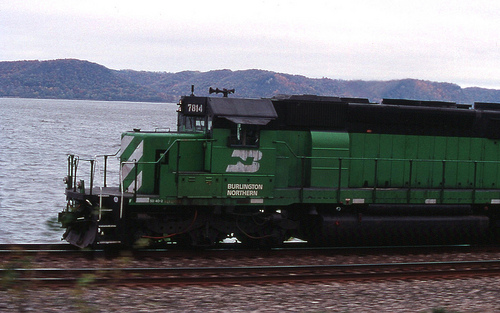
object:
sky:
[0, 0, 500, 91]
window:
[192, 119, 203, 130]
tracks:
[0, 259, 497, 280]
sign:
[225, 149, 264, 173]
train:
[57, 84, 498, 254]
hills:
[0, 58, 499, 109]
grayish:
[7, 276, 41, 283]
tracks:
[0, 240, 500, 254]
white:
[50, 51, 70, 56]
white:
[134, 153, 140, 155]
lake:
[0, 97, 309, 244]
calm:
[0, 97, 300, 242]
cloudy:
[0, 0, 499, 90]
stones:
[16, 307, 37, 311]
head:
[58, 86, 309, 250]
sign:
[226, 183, 264, 197]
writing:
[226, 181, 262, 195]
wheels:
[232, 211, 296, 246]